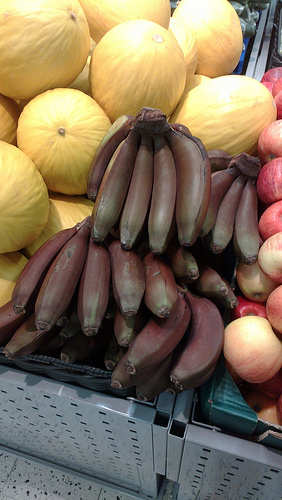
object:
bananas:
[170, 290, 225, 391]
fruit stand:
[0, 0, 282, 499]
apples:
[223, 314, 282, 384]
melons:
[168, 75, 278, 158]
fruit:
[87, 114, 134, 203]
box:
[199, 241, 282, 449]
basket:
[0, 347, 178, 497]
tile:
[0, 449, 102, 499]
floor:
[0, 442, 152, 498]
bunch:
[87, 107, 212, 256]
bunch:
[197, 151, 261, 264]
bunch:
[11, 213, 178, 338]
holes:
[128, 419, 135, 424]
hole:
[203, 448, 211, 452]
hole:
[43, 395, 50, 399]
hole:
[236, 458, 245, 462]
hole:
[196, 469, 203, 474]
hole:
[17, 386, 24, 391]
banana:
[107, 239, 146, 319]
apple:
[261, 66, 282, 83]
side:
[0, 366, 281, 499]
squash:
[0, 139, 50, 254]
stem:
[134, 106, 170, 136]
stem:
[58, 127, 65, 135]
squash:
[1, 0, 90, 101]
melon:
[17, 86, 112, 196]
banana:
[90, 128, 139, 246]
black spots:
[57, 478, 59, 482]